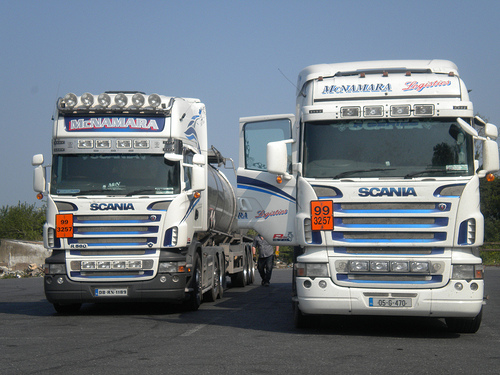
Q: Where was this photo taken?
A: On a road.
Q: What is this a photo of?
A: Two trucks.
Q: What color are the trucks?
A: White.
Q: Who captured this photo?
A: A photographer.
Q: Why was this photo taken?
A: To show trucks.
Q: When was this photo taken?
A: In the daytime.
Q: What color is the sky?
A: Blue.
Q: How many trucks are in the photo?
A: Two.